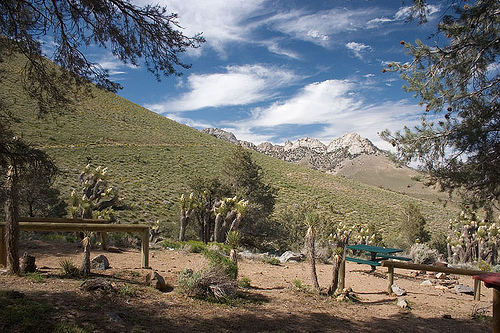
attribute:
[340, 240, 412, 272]
bench — green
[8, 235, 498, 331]
soil — dry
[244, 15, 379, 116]
sky — blue, cloudy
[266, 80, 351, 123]
clouds — white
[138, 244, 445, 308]
dirt — brown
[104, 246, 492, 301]
sand — brown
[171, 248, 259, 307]
bush — green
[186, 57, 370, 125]
clouds — white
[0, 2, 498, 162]
sky — blue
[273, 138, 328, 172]
mountain — white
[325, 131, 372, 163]
mountain — white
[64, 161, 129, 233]
cactus — green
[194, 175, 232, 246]
tree — green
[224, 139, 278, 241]
tree — green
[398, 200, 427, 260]
tree — green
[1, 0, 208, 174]
tree — green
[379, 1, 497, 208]
tree — green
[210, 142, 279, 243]
tree — bushy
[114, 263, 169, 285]
rock — earthy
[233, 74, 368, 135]
cloud — white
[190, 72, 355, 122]
clouds — white, wispy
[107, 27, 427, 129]
sky — blue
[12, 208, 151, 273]
post — brown, wooden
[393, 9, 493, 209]
tree — green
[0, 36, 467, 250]
hillside — green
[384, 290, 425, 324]
rock — Light colored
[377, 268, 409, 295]
rock — Light colored